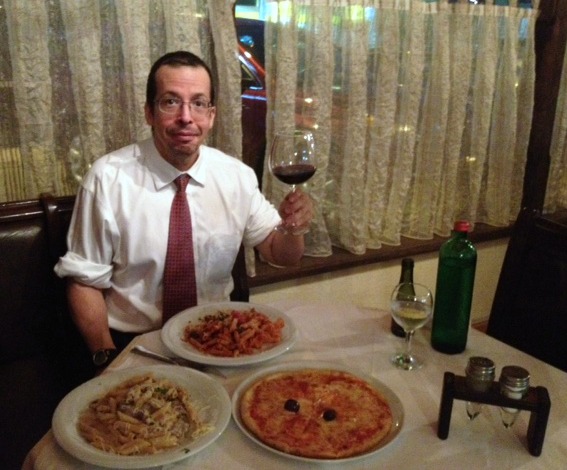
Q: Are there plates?
A: Yes, there is a plate.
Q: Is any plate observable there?
A: Yes, there is a plate.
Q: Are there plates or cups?
A: Yes, there is a plate.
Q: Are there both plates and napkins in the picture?
A: No, there is a plate but no napkins.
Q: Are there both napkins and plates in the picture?
A: No, there is a plate but no napkins.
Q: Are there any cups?
A: No, there are no cups.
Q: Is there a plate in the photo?
A: Yes, there is a plate.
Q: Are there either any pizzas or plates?
A: Yes, there is a plate.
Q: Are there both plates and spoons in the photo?
A: No, there is a plate but no spoons.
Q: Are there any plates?
A: Yes, there is a plate.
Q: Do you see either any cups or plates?
A: Yes, there is a plate.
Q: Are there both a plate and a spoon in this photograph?
A: No, there is a plate but no spoons.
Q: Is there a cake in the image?
A: No, there are no cakes.